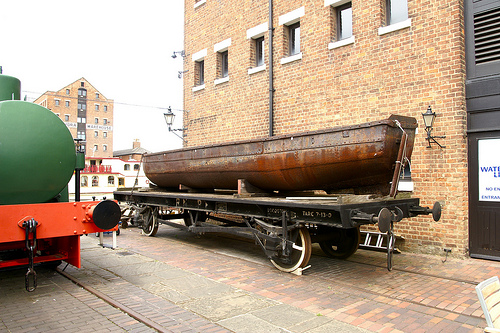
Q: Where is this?
A: This is at the road.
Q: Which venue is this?
A: This is a road.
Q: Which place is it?
A: It is a road.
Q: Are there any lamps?
A: Yes, there is a lamp.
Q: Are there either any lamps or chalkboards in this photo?
A: Yes, there is a lamp.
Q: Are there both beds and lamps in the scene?
A: No, there is a lamp but no beds.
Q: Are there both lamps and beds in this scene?
A: No, there is a lamp but no beds.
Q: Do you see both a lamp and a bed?
A: No, there is a lamp but no beds.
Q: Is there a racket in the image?
A: No, there are no rackets.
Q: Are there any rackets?
A: No, there are no rackets.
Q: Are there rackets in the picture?
A: No, there are no rackets.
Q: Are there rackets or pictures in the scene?
A: No, there are no rackets or pictures.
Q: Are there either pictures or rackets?
A: No, there are no rackets or pictures.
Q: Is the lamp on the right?
A: Yes, the lamp is on the right of the image.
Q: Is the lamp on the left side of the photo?
A: No, the lamp is on the right of the image.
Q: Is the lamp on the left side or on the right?
A: The lamp is on the right of the image.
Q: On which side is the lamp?
A: The lamp is on the right of the image.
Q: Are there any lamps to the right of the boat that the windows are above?
A: Yes, there is a lamp to the right of the boat.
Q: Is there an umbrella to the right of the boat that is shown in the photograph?
A: No, there is a lamp to the right of the boat.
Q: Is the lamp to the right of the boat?
A: Yes, the lamp is to the right of the boat.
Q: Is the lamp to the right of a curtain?
A: No, the lamp is to the right of the boat.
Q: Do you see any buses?
A: No, there are no buses.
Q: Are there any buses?
A: No, there are no buses.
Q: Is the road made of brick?
A: Yes, the road is made of brick.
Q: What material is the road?
A: The road is made of brick.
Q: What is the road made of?
A: The road is made of brick.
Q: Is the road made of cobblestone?
A: No, the road is made of brick.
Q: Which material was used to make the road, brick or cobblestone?
A: The road is made of brick.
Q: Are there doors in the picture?
A: Yes, there is a door.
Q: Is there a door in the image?
A: Yes, there is a door.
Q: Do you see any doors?
A: Yes, there is a door.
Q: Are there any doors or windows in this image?
A: Yes, there is a door.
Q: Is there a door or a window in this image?
A: Yes, there is a door.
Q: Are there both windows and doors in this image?
A: Yes, there are both a door and windows.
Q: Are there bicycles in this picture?
A: No, there are no bicycles.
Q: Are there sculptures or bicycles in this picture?
A: No, there are no bicycles or sculptures.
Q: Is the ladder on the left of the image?
A: No, the ladder is on the right of the image.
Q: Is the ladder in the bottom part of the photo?
A: Yes, the ladder is in the bottom of the image.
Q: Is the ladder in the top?
A: No, the ladder is in the bottom of the image.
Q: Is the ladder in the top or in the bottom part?
A: The ladder is in the bottom of the image.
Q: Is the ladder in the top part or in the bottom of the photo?
A: The ladder is in the bottom of the image.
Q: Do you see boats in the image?
A: Yes, there is a boat.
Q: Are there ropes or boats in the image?
A: Yes, there is a boat.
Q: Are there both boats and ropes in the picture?
A: No, there is a boat but no ropes.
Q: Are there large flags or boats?
A: Yes, there is a large boat.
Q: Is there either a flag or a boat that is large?
A: Yes, the boat is large.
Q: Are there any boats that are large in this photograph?
A: Yes, there is a large boat.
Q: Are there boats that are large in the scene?
A: Yes, there is a large boat.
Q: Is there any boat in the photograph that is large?
A: Yes, there is a boat that is large.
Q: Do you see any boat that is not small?
A: Yes, there is a large boat.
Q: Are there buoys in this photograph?
A: No, there are no buoys.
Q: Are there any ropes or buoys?
A: No, there are no buoys or ropes.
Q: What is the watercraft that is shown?
A: The watercraft is a boat.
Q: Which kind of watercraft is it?
A: The watercraft is a boat.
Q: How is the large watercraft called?
A: The watercraft is a boat.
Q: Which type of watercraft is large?
A: The watercraft is a boat.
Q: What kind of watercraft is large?
A: The watercraft is a boat.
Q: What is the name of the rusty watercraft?
A: The watercraft is a boat.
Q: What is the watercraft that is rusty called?
A: The watercraft is a boat.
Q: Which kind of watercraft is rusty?
A: The watercraft is a boat.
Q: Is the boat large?
A: Yes, the boat is large.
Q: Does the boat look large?
A: Yes, the boat is large.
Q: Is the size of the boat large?
A: Yes, the boat is large.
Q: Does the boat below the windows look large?
A: Yes, the boat is large.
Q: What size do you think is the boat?
A: The boat is large.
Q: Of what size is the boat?
A: The boat is large.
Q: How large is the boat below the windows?
A: The boat is large.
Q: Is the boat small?
A: No, the boat is large.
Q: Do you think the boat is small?
A: No, the boat is large.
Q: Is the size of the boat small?
A: No, the boat is large.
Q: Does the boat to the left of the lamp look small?
A: No, the boat is large.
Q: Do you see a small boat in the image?
A: No, there is a boat but it is large.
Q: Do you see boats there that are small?
A: No, there is a boat but it is large.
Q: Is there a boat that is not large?
A: No, there is a boat but it is large.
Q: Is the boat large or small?
A: The boat is large.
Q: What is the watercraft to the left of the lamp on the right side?
A: The watercraft is a boat.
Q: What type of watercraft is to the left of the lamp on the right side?
A: The watercraft is a boat.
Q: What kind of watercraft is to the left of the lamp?
A: The watercraft is a boat.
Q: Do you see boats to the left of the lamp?
A: Yes, there is a boat to the left of the lamp.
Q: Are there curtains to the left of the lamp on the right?
A: No, there is a boat to the left of the lamp.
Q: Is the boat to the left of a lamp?
A: Yes, the boat is to the left of a lamp.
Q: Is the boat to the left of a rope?
A: No, the boat is to the left of a lamp.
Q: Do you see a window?
A: Yes, there is a window.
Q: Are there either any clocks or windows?
A: Yes, there is a window.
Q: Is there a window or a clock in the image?
A: Yes, there is a window.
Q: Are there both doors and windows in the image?
A: Yes, there are both a window and a door.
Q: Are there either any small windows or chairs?
A: Yes, there is a small window.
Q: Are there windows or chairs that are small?
A: Yes, the window is small.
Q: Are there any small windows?
A: Yes, there is a small window.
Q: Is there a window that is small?
A: Yes, there is a window that is small.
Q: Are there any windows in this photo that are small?
A: Yes, there is a window that is small.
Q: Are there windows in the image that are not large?
A: Yes, there is a small window.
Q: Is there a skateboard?
A: No, there are no skateboards.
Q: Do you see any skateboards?
A: No, there are no skateboards.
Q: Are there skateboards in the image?
A: No, there are no skateboards.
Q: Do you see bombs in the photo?
A: No, there are no bombs.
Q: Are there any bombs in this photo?
A: No, there are no bombs.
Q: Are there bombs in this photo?
A: No, there are no bombs.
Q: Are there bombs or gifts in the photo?
A: No, there are no bombs or gifts.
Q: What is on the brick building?
A: The pole is on the building.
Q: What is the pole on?
A: The pole is on the building.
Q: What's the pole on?
A: The pole is on the building.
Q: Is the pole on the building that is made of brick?
A: Yes, the pole is on the building.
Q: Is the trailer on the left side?
A: Yes, the trailer is on the left of the image.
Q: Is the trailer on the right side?
A: No, the trailer is on the left of the image.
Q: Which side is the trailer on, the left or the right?
A: The trailer is on the left of the image.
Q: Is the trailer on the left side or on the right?
A: The trailer is on the left of the image.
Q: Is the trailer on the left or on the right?
A: The trailer is on the left of the image.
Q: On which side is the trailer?
A: The trailer is on the left of the image.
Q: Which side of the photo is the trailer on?
A: The trailer is on the left of the image.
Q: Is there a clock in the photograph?
A: No, there are no clocks.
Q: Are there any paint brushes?
A: No, there are no paint brushes.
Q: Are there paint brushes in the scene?
A: No, there are no paint brushes.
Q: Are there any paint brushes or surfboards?
A: No, there are no paint brushes or surfboards.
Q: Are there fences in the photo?
A: No, there are no fences.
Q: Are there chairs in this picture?
A: Yes, there is a chair.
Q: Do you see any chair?
A: Yes, there is a chair.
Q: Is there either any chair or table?
A: Yes, there is a chair.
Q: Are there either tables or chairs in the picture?
A: Yes, there is a chair.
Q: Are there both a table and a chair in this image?
A: No, there is a chair but no tables.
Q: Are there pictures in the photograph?
A: No, there are no pictures.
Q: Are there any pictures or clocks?
A: No, there are no pictures or clocks.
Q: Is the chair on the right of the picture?
A: Yes, the chair is on the right of the image.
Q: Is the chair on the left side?
A: No, the chair is on the right of the image.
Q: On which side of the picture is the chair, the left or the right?
A: The chair is on the right of the image.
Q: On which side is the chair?
A: The chair is on the right of the image.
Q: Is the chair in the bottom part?
A: Yes, the chair is in the bottom of the image.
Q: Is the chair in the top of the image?
A: No, the chair is in the bottom of the image.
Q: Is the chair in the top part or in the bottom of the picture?
A: The chair is in the bottom of the image.